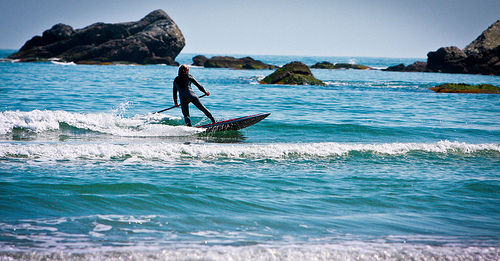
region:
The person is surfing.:
[136, 60, 296, 145]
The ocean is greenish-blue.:
[7, 51, 497, 253]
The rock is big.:
[6, 5, 188, 63]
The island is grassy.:
[427, 78, 498, 103]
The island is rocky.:
[385, 8, 497, 77]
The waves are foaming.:
[2, 104, 491, 166]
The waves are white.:
[4, 105, 495, 164]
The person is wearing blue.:
[169, 62, 218, 121]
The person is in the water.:
[135, 48, 292, 189]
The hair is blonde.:
[172, 56, 198, 78]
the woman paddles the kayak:
[113, 8, 330, 190]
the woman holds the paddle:
[117, 27, 304, 161]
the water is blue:
[333, 110, 442, 202]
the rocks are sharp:
[82, 6, 497, 213]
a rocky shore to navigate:
[21, 13, 492, 173]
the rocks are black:
[74, 14, 427, 214]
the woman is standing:
[59, 11, 388, 175]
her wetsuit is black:
[144, 65, 204, 110]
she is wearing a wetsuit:
[129, 39, 301, 169]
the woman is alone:
[108, 7, 463, 194]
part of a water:
[257, 181, 292, 222]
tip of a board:
[250, 95, 287, 133]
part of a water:
[318, 145, 364, 207]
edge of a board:
[210, 92, 247, 123]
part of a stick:
[154, 95, 176, 126]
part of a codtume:
[175, 73, 219, 140]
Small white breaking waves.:
[282, 135, 362, 165]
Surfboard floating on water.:
[200, 110, 272, 161]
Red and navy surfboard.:
[200, 100, 251, 145]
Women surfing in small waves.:
[165, 57, 225, 157]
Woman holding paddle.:
[157, 62, 213, 149]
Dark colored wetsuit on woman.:
[165, 60, 230, 155]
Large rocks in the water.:
[395, 6, 492, 101]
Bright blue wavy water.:
[315, 85, 365, 140]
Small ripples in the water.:
[326, 87, 408, 127]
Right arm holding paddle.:
[181, 65, 219, 105]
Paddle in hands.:
[164, 54, 238, 160]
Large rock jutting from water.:
[45, 4, 161, 89]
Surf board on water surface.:
[177, 101, 276, 138]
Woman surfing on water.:
[169, 58, 213, 162]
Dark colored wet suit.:
[166, 55, 243, 164]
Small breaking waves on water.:
[65, 100, 150, 183]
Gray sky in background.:
[326, 12, 398, 87]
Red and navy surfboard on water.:
[180, 108, 282, 151]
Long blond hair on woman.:
[167, 52, 214, 124]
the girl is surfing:
[146, 63, 288, 139]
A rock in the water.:
[434, 79, 493, 92]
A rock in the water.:
[261, 59, 318, 91]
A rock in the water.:
[17, 9, 187, 69]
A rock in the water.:
[192, 52, 204, 62]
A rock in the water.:
[313, 58, 330, 67]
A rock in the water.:
[336, 61, 366, 70]